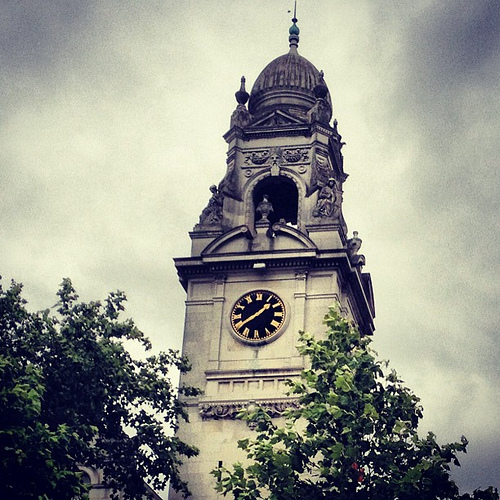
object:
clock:
[229, 285, 289, 346]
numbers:
[252, 326, 260, 339]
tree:
[214, 302, 470, 500]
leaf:
[333, 376, 351, 390]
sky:
[2, 1, 195, 159]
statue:
[316, 177, 341, 216]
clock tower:
[170, 1, 375, 499]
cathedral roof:
[248, 0, 333, 124]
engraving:
[243, 144, 314, 179]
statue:
[199, 184, 222, 225]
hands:
[237, 309, 261, 326]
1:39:
[232, 292, 284, 338]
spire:
[289, 1, 300, 55]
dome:
[248, 51, 333, 118]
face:
[268, 152, 283, 168]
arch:
[249, 167, 298, 240]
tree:
[1, 275, 206, 500]